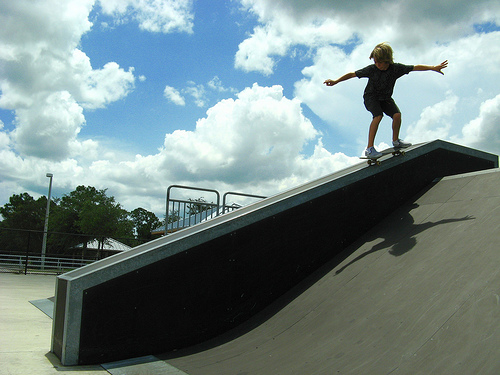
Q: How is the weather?
A: It is sunny.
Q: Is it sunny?
A: Yes, it is sunny.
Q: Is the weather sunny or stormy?
A: It is sunny.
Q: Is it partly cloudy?
A: No, it is sunny.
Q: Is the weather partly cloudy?
A: No, it is sunny.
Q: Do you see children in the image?
A: Yes, there is a child.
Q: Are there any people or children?
A: Yes, there is a child.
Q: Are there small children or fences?
A: Yes, there is a small child.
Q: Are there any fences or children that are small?
A: Yes, the child is small.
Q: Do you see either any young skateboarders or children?
A: Yes, there is a young child.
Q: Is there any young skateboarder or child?
A: Yes, there is a young child.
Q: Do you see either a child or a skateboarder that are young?
A: Yes, the child is young.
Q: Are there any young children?
A: Yes, there is a young child.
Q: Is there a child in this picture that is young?
A: Yes, there is a child that is young.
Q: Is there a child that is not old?
A: Yes, there is an young child.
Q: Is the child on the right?
A: Yes, the child is on the right of the image.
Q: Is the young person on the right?
A: Yes, the child is on the right of the image.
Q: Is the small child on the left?
A: No, the kid is on the right of the image.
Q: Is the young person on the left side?
A: No, the kid is on the right of the image.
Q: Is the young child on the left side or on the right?
A: The kid is on the right of the image.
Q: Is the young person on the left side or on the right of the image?
A: The kid is on the right of the image.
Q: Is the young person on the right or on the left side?
A: The kid is on the right of the image.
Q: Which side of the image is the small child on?
A: The child is on the right of the image.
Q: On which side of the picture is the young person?
A: The child is on the right of the image.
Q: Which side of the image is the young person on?
A: The child is on the right of the image.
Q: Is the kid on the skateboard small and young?
A: Yes, the child is small and young.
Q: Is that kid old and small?
A: No, the kid is small but young.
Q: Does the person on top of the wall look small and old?
A: No, the kid is small but young.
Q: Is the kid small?
A: Yes, the kid is small.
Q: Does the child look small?
A: Yes, the child is small.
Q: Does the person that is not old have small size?
A: Yes, the child is small.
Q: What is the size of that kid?
A: The kid is small.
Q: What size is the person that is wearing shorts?
A: The kid is small.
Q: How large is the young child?
A: The kid is small.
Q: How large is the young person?
A: The kid is small.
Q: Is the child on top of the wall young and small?
A: Yes, the kid is young and small.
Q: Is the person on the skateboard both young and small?
A: Yes, the kid is young and small.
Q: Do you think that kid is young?
A: Yes, the kid is young.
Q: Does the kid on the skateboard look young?
A: Yes, the kid is young.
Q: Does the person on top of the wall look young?
A: Yes, the kid is young.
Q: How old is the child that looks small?
A: The child is young.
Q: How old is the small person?
A: The child is young.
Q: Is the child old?
A: No, the child is young.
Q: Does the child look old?
A: No, the child is young.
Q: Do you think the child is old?
A: No, the child is young.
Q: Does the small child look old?
A: No, the kid is young.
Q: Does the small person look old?
A: No, the kid is young.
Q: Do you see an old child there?
A: No, there is a child but he is young.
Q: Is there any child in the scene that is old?
A: No, there is a child but he is young.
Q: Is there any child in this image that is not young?
A: No, there is a child but he is young.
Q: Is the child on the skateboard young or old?
A: The child is young.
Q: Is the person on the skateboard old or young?
A: The child is young.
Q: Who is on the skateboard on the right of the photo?
A: The kid is on the skateboard.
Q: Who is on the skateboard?
A: The kid is on the skateboard.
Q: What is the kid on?
A: The kid is on the skateboard.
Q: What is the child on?
A: The kid is on the skateboard.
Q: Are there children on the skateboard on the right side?
A: Yes, there is a child on the skateboard.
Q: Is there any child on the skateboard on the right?
A: Yes, there is a child on the skateboard.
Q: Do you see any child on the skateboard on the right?
A: Yes, there is a child on the skateboard.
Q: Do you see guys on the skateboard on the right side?
A: No, there is a child on the skateboard.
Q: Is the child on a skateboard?
A: Yes, the child is on a skateboard.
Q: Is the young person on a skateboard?
A: Yes, the child is on a skateboard.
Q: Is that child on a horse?
A: No, the child is on a skateboard.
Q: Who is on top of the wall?
A: The child is on top of the wall.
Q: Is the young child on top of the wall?
A: Yes, the kid is on top of the wall.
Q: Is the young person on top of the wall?
A: Yes, the kid is on top of the wall.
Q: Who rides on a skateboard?
A: The kid rides on a skateboard.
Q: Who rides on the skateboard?
A: The kid rides on a skateboard.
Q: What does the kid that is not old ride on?
A: The child rides on a skateboard.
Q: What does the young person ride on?
A: The child rides on a skateboard.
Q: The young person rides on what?
A: The child rides on a skateboard.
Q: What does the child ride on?
A: The child rides on a skateboard.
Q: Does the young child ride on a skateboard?
A: Yes, the child rides on a skateboard.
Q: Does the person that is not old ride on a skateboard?
A: Yes, the child rides on a skateboard.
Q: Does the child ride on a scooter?
A: No, the child rides on a skateboard.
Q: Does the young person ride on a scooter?
A: No, the child rides on a skateboard.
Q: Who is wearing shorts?
A: The kid is wearing shorts.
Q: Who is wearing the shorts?
A: The kid is wearing shorts.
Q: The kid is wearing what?
A: The kid is wearing shorts.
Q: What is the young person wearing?
A: The kid is wearing shorts.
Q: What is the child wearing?
A: The kid is wearing shorts.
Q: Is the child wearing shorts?
A: Yes, the child is wearing shorts.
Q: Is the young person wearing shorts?
A: Yes, the child is wearing shorts.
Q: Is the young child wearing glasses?
A: No, the kid is wearing shorts.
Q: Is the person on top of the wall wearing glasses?
A: No, the kid is wearing shorts.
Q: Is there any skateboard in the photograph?
A: Yes, there is a skateboard.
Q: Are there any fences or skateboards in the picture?
A: Yes, there is a skateboard.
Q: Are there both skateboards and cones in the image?
A: No, there is a skateboard but no cones.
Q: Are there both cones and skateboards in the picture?
A: No, there is a skateboard but no cones.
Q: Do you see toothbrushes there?
A: No, there are no toothbrushes.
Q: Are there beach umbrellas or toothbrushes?
A: No, there are no toothbrushes or beach umbrellas.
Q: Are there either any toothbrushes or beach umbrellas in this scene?
A: No, there are no toothbrushes or beach umbrellas.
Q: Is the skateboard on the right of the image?
A: Yes, the skateboard is on the right of the image.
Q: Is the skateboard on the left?
A: No, the skateboard is on the right of the image.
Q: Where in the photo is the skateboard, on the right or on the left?
A: The skateboard is on the right of the image.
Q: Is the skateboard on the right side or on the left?
A: The skateboard is on the right of the image.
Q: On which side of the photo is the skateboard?
A: The skateboard is on the right of the image.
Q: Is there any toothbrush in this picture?
A: No, there are no toothbrushes.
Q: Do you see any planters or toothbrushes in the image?
A: No, there are no toothbrushes or planters.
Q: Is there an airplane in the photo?
A: No, there are no airplanes.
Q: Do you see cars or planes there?
A: No, there are no planes or cars.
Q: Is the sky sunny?
A: Yes, the sky is sunny.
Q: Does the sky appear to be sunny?
A: Yes, the sky is sunny.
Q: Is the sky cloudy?
A: No, the sky is sunny.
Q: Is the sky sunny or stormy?
A: The sky is sunny.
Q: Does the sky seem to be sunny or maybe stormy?
A: The sky is sunny.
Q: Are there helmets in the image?
A: No, there are no helmets.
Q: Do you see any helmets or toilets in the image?
A: No, there are no helmets or toilets.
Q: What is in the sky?
A: The clouds are in the sky.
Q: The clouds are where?
A: The clouds are in the sky.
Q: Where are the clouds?
A: The clouds are in the sky.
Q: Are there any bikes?
A: No, there are no bikes.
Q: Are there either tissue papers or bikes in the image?
A: No, there are no bikes or tissue papers.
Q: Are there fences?
A: Yes, there is a fence.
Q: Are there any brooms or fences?
A: Yes, there is a fence.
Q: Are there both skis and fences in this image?
A: No, there is a fence but no skis.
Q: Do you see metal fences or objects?
A: Yes, there is a metal fence.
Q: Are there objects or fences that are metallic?
A: Yes, the fence is metallic.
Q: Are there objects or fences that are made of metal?
A: Yes, the fence is made of metal.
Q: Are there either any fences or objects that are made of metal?
A: Yes, the fence is made of metal.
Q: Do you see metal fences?
A: Yes, there is a metal fence.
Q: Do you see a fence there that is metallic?
A: Yes, there is a fence that is metallic.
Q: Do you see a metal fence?
A: Yes, there is a fence that is made of metal.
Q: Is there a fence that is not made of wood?
A: Yes, there is a fence that is made of metal.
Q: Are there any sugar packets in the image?
A: No, there are no sugar packets.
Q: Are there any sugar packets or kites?
A: No, there are no sugar packets or kites.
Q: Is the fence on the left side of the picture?
A: Yes, the fence is on the left of the image.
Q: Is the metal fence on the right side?
A: No, the fence is on the left of the image.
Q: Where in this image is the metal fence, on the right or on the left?
A: The fence is on the left of the image.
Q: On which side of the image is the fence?
A: The fence is on the left of the image.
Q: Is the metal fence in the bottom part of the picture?
A: Yes, the fence is in the bottom of the image.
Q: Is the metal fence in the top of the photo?
A: No, the fence is in the bottom of the image.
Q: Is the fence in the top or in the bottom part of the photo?
A: The fence is in the bottom of the image.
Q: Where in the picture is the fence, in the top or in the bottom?
A: The fence is in the bottom of the image.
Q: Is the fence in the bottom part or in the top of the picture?
A: The fence is in the bottom of the image.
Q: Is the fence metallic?
A: Yes, the fence is metallic.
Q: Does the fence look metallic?
A: Yes, the fence is metallic.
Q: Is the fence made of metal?
A: Yes, the fence is made of metal.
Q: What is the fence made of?
A: The fence is made of metal.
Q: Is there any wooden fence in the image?
A: No, there is a fence but it is metallic.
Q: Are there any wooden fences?
A: No, there is a fence but it is metallic.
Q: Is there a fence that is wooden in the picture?
A: No, there is a fence but it is metallic.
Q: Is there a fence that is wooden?
A: No, there is a fence but it is metallic.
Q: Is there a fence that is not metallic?
A: No, there is a fence but it is metallic.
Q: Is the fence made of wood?
A: No, the fence is made of metal.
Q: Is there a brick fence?
A: No, there is a fence but it is made of metal.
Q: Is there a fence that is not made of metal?
A: No, there is a fence but it is made of metal.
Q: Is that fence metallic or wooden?
A: The fence is metallic.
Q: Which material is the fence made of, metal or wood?
A: The fence is made of metal.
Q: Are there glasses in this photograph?
A: No, there are no glasses.